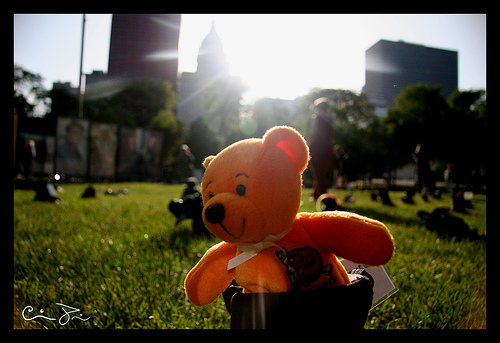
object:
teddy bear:
[185, 126, 394, 306]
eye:
[236, 184, 245, 195]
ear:
[260, 126, 309, 172]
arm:
[305, 211, 394, 265]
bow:
[227, 234, 285, 270]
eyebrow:
[236, 173, 249, 177]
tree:
[383, 85, 459, 189]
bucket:
[224, 274, 373, 330]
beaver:
[275, 246, 333, 286]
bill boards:
[55, 118, 89, 175]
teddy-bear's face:
[202, 173, 254, 245]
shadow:
[342, 208, 416, 225]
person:
[416, 207, 477, 243]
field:
[7, 183, 488, 330]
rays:
[140, 7, 406, 130]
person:
[307, 97, 335, 200]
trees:
[107, 77, 184, 175]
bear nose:
[205, 203, 226, 224]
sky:
[177, 15, 485, 104]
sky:
[9, 12, 112, 113]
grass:
[14, 181, 484, 330]